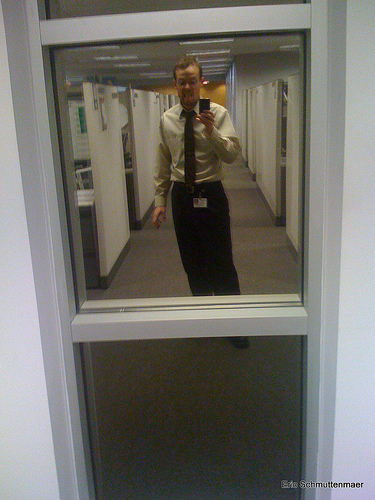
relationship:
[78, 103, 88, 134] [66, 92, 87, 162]
blue paper on a wall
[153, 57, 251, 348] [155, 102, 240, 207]
male wearing shirt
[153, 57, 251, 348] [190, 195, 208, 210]
male wearing identification badge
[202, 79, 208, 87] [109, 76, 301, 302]
sign at end of hallway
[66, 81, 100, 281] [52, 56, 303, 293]
cubicle in office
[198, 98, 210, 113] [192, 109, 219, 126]
cell phone held by hand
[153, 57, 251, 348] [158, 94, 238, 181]
male wearing shirt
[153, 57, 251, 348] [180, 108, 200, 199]
male wearing tie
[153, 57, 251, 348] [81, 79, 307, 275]
male between cubicles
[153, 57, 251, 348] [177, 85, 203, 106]
male sticking out tongue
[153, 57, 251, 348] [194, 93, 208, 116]
male holding phone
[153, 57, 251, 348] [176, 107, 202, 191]
male wearing necktie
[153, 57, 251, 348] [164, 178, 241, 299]
male wearing pants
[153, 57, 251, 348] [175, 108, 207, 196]
male wearing a tie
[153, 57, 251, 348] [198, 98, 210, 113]
male looks at cell phone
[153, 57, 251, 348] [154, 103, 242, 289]
male wearing clothes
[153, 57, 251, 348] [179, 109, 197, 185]
male wearing a necktie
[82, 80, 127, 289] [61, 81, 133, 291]
wall of a cubicle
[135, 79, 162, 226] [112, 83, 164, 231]
wall of a cubicle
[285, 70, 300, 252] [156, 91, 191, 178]
wall of a cubicle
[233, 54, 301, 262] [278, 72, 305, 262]
wall of a cubicle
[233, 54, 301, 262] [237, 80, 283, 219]
wall of a cubicle